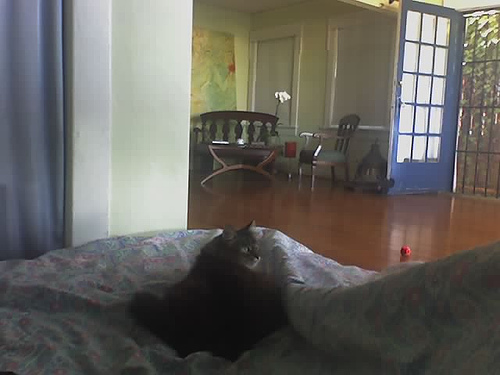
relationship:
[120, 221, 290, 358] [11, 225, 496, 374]
cat on bed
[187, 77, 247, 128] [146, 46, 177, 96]
painting on wall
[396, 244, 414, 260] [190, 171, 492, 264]
ball on floor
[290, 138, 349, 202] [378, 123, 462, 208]
chair by door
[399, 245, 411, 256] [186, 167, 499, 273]
ball on floor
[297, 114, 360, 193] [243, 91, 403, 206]
chair near wall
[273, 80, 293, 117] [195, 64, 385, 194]
flower near wall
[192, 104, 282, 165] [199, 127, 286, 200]
bench behind table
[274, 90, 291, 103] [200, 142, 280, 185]
flower on coffee table